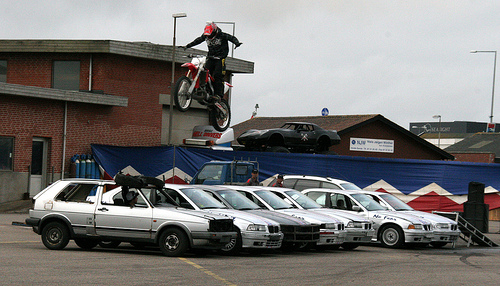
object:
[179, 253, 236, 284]
line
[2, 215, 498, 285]
ground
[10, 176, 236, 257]
car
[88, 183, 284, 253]
car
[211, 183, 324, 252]
car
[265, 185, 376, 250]
car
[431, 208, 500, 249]
ramp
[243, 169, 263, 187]
guard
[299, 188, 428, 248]
cars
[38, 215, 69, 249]
tire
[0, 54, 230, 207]
wall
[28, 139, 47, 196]
closed door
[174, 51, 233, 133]
bike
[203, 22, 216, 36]
helmet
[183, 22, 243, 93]
man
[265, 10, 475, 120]
sky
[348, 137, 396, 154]
sign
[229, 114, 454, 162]
building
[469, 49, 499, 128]
pole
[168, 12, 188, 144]
pole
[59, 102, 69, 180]
pole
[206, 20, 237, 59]
pole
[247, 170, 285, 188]
people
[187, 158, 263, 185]
truck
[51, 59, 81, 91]
window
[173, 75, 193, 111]
tire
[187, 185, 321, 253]
car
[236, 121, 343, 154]
black car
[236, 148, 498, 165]
display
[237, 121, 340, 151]
car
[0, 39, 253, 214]
building